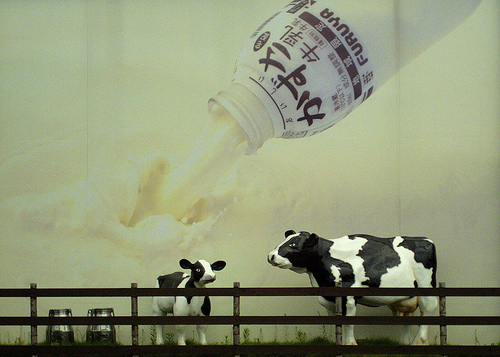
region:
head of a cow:
[269, 211, 321, 275]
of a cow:
[173, 240, 248, 288]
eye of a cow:
[280, 233, 305, 249]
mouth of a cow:
[258, 250, 280, 264]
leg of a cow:
[320, 293, 377, 348]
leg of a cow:
[391, 300, 456, 351]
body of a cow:
[330, 205, 445, 307]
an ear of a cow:
[172, 253, 196, 285]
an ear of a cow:
[205, 256, 236, 270]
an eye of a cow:
[195, 262, 206, 270]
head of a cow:
[178, 246, 226, 293]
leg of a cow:
[145, 298, 174, 349]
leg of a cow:
[179, 307, 199, 355]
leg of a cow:
[196, 298, 219, 355]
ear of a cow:
[168, 247, 197, 279]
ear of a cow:
[206, 254, 237, 276]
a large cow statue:
[274, 224, 439, 344]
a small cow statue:
[153, 260, 221, 344]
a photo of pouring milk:
[123, 0, 483, 243]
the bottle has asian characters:
[259, 26, 324, 123]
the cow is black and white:
[272, 228, 438, 345]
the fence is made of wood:
[0, 280, 499, 355]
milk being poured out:
[28, 107, 240, 267]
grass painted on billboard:
[0, 308, 498, 345]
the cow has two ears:
[181, 257, 225, 266]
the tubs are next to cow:
[43, 306, 114, 342]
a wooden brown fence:
[2, 282, 499, 346]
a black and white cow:
[267, 226, 439, 350]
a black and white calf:
[154, 256, 225, 349]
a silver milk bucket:
[46, 303, 119, 341]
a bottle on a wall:
[194, 0, 499, 184]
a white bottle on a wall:
[206, 1, 481, 156]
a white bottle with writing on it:
[205, 3, 379, 163]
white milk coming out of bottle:
[110, 120, 240, 235]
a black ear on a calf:
[178, 260, 193, 270]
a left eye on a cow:
[284, 238, 299, 253]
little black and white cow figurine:
[266, 219, 446, 349]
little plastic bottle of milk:
[71, 12, 463, 226]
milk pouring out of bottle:
[40, 85, 289, 257]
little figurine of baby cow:
[148, 252, 227, 344]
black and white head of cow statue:
[266, 224, 316, 274]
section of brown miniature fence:
[4, 277, 495, 355]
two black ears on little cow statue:
[176, 256, 228, 271]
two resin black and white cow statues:
[151, 226, 442, 347]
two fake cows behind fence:
[148, 225, 445, 351]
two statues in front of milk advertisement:
[147, 7, 440, 351]